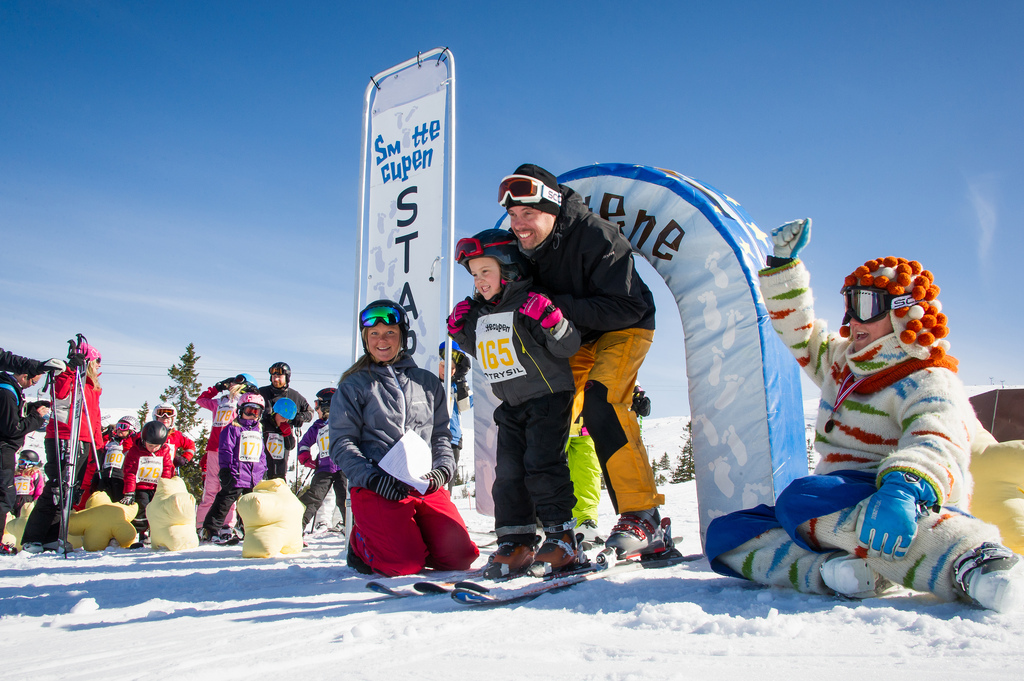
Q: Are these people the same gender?
A: Yes, all the people are female.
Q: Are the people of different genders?
A: No, all the people are female.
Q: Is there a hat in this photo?
A: Yes, there is a hat.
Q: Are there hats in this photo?
A: Yes, there is a hat.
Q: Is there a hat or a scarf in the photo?
A: Yes, there is a hat.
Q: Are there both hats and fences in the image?
A: No, there is a hat but no fences.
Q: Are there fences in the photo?
A: No, there are no fences.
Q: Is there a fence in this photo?
A: No, there are no fences.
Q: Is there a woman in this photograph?
A: Yes, there is a woman.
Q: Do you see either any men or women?
A: Yes, there is a woman.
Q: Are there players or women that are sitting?
A: Yes, the woman is sitting.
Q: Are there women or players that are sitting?
A: Yes, the woman is sitting.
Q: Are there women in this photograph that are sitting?
A: Yes, there is a woman that is sitting.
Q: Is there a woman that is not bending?
A: Yes, there is a woman that is sitting.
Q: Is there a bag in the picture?
A: No, there are no bags.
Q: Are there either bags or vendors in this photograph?
A: No, there are no bags or vendors.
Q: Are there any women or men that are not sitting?
A: No, there is a woman but she is sitting.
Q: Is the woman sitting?
A: Yes, the woman is sitting.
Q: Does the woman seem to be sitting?
A: Yes, the woman is sitting.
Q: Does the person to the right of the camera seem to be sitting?
A: Yes, the woman is sitting.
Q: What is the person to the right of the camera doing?
A: The woman is sitting.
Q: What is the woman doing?
A: The woman is sitting.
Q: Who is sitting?
A: The woman is sitting.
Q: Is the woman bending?
A: No, the woman is sitting.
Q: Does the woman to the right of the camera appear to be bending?
A: No, the woman is sitting.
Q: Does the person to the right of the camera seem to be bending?
A: No, the woman is sitting.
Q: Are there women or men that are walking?
A: No, there is a woman but she is sitting.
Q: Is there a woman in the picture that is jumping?
A: No, there is a woman but she is sitting.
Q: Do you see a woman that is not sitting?
A: No, there is a woman but she is sitting.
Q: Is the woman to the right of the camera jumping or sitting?
A: The woman is sitting.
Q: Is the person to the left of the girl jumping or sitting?
A: The woman is sitting.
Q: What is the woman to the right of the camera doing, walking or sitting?
A: The woman is sitting.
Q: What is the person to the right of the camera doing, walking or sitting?
A: The woman is sitting.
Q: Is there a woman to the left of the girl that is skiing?
A: Yes, there is a woman to the left of the girl.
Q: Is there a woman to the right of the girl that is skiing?
A: No, the woman is to the left of the girl.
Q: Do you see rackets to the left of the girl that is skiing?
A: No, there is a woman to the left of the girl.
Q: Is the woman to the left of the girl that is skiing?
A: Yes, the woman is to the left of the girl.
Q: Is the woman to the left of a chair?
A: No, the woman is to the left of the girl.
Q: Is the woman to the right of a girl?
A: No, the woman is to the left of a girl.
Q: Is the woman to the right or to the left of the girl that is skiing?
A: The woman is to the left of the girl.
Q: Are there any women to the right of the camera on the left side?
A: Yes, there is a woman to the right of the camera.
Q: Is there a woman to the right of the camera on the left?
A: Yes, there is a woman to the right of the camera.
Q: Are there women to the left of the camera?
A: No, the woman is to the right of the camera.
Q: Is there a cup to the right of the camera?
A: No, there is a woman to the right of the camera.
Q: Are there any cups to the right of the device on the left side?
A: No, there is a woman to the right of the camera.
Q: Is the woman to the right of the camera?
A: Yes, the woman is to the right of the camera.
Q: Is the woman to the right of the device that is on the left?
A: Yes, the woman is to the right of the camera.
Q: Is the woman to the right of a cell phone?
A: No, the woman is to the right of the camera.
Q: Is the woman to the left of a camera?
A: No, the woman is to the right of a camera.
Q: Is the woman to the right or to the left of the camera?
A: The woman is to the right of the camera.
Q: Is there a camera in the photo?
A: Yes, there is a camera.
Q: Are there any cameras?
A: Yes, there is a camera.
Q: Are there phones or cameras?
A: Yes, there is a camera.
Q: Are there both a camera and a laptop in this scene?
A: No, there is a camera but no laptops.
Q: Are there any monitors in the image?
A: No, there are no monitors.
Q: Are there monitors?
A: No, there are no monitors.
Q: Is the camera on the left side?
A: Yes, the camera is on the left of the image.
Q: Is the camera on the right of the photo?
A: No, the camera is on the left of the image.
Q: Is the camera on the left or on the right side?
A: The camera is on the left of the image.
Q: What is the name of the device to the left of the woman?
A: The device is a camera.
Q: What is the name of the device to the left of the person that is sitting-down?
A: The device is a camera.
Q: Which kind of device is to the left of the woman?
A: The device is a camera.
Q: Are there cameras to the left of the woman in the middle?
A: Yes, there is a camera to the left of the woman.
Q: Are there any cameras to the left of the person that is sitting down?
A: Yes, there is a camera to the left of the woman.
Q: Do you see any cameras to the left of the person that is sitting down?
A: Yes, there is a camera to the left of the woman.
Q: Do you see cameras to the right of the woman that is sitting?
A: No, the camera is to the left of the woman.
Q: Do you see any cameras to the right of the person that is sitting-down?
A: No, the camera is to the left of the woman.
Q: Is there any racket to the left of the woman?
A: No, there is a camera to the left of the woman.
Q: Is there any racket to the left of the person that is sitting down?
A: No, there is a camera to the left of the woman.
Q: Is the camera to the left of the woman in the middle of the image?
A: Yes, the camera is to the left of the woman.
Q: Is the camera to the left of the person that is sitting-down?
A: Yes, the camera is to the left of the woman.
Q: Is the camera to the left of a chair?
A: No, the camera is to the left of the woman.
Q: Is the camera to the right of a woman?
A: No, the camera is to the left of a woman.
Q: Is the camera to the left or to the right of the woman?
A: The camera is to the left of the woman.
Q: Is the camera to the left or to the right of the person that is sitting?
A: The camera is to the left of the woman.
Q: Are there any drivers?
A: No, there are no drivers.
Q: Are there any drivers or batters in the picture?
A: No, there are no drivers or batters.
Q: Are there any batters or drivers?
A: No, there are no drivers or batters.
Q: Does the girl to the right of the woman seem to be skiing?
A: Yes, the girl is skiing.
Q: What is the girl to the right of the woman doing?
A: The girl is skiing.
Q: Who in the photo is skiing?
A: The girl is skiing.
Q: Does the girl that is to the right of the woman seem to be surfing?
A: No, the girl is skiing.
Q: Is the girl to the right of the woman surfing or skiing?
A: The girl is skiing.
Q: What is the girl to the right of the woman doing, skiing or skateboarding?
A: The girl is skiing.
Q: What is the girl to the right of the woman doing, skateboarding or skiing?
A: The girl is skiing.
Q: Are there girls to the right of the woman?
A: Yes, there is a girl to the right of the woman.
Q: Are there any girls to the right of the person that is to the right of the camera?
A: Yes, there is a girl to the right of the woman.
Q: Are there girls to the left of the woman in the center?
A: No, the girl is to the right of the woman.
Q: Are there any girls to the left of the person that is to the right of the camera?
A: No, the girl is to the right of the woman.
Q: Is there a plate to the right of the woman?
A: No, there is a girl to the right of the woman.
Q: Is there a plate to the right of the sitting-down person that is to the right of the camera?
A: No, there is a girl to the right of the woman.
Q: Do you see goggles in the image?
A: Yes, there are goggles.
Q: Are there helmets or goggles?
A: Yes, there are goggles.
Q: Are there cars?
A: No, there are no cars.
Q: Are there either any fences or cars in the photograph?
A: No, there are no cars or fences.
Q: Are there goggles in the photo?
A: Yes, there are goggles.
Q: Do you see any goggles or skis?
A: Yes, there are goggles.